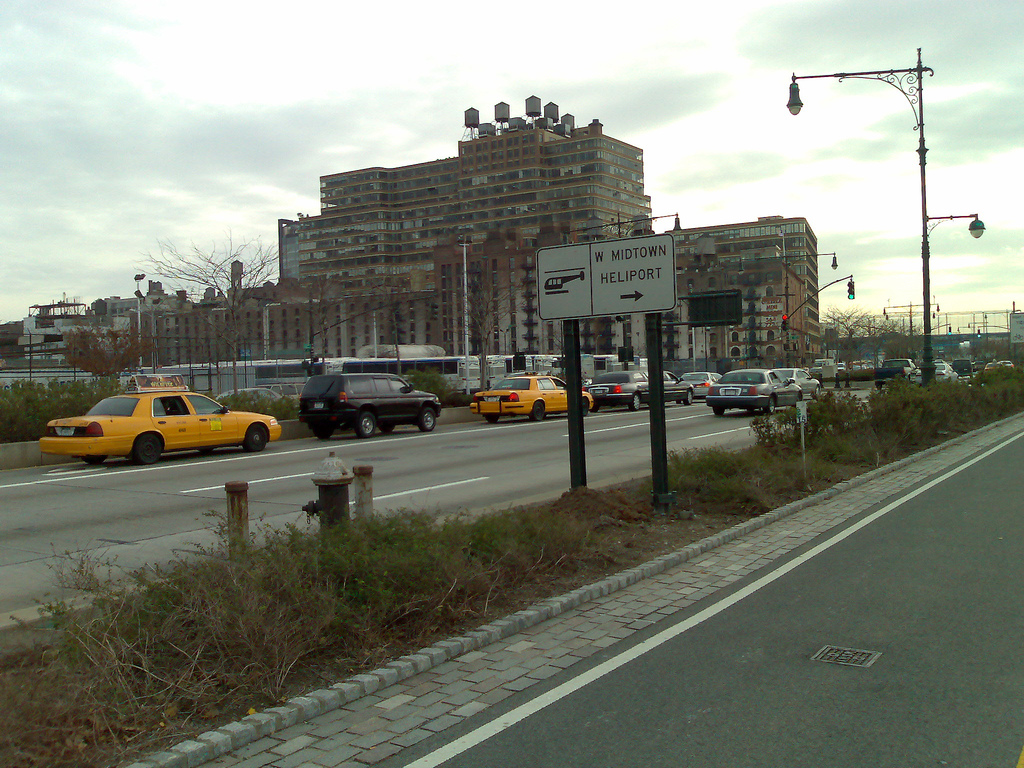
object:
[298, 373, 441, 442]
blacktruck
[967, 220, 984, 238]
light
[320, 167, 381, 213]
wall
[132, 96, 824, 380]
building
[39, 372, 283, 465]
cab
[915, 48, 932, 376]
pole